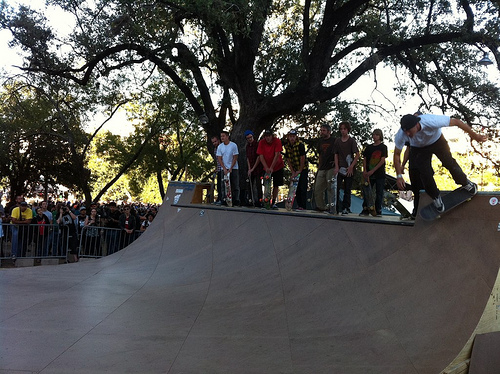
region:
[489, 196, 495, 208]
white mark is spotted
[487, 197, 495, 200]
white mark is spotted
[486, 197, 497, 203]
white mark is spotted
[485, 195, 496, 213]
white mark is spotted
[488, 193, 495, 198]
white mark is spotted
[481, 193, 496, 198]
white mark is spotted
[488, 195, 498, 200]
white mark is spotted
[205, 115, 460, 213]
the skateboarders on the ramp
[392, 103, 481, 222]
the man skateboarding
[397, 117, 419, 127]
the skateboarders black hat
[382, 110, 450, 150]
the white short sleeved shirt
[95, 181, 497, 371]
the skateboarding ramp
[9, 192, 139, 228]
the spectators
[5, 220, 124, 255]
the metal barricades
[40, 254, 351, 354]
the lines on the ramp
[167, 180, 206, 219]
the stickers on the ramp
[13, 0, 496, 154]
the big tree behind the ramp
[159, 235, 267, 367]
a ramp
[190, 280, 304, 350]
a ramp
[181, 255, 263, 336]
a ramp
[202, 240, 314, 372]
a ramp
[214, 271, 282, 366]
a ramp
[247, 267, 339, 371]
a ramp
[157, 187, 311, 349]
a ramp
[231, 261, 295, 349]
a ramp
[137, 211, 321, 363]
the ramp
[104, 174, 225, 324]
the ramp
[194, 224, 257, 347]
the ramp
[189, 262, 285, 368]
the ramp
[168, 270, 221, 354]
the ramp